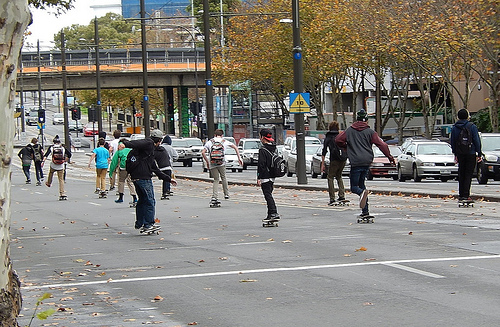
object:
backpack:
[260, 144, 289, 178]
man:
[255, 128, 291, 223]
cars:
[394, 140, 461, 183]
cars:
[365, 144, 405, 181]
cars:
[285, 143, 324, 178]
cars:
[235, 137, 266, 171]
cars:
[170, 138, 194, 168]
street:
[10, 95, 500, 326]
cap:
[259, 128, 275, 142]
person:
[199, 128, 245, 204]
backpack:
[209, 137, 227, 166]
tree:
[435, 0, 500, 109]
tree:
[300, 0, 372, 131]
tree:
[211, 0, 298, 130]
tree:
[383, 0, 450, 141]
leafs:
[150, 294, 166, 304]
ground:
[0, 89, 500, 327]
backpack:
[451, 122, 475, 156]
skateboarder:
[448, 106, 486, 204]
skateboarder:
[115, 127, 179, 234]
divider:
[388, 181, 459, 187]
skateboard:
[261, 217, 281, 228]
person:
[333, 108, 397, 220]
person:
[116, 128, 181, 234]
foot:
[357, 188, 372, 210]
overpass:
[13, 39, 240, 89]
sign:
[288, 92, 311, 114]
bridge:
[12, 39, 235, 94]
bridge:
[14, 40, 230, 94]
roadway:
[7, 88, 500, 327]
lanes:
[16, 250, 500, 293]